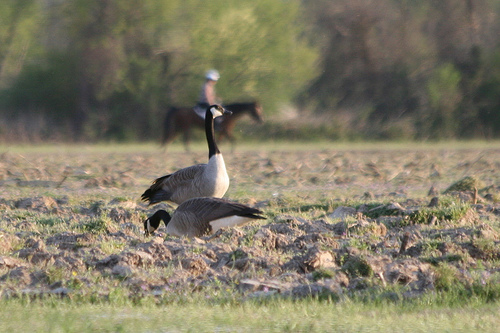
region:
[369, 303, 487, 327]
this is the grass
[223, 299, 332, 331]
the grass is green in color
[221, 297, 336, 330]
the grass is short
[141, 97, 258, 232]
these are birds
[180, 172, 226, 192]
the feathers are white in color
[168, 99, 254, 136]
this is a horse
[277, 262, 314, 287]
these are rocks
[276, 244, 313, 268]
the rocks are grey in color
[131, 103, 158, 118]
these are trees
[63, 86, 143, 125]
the trees are green in color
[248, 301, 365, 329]
Green grass on the ground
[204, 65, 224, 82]
Person wearing a white helmet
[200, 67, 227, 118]
Person sitting on a horse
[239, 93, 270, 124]
Horse head looking right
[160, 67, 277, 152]
Horse with a rider walking right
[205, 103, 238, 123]
Canadian goose head looking right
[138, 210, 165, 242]
Canadian goose eating grass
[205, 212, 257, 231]
White underside of a goose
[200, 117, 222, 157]
Canadian goose's black neck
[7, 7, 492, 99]
Trees behind a field of grass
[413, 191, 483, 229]
part of a ground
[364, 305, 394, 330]
part of some grass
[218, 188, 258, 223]
part of a tail wing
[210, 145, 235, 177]
part of a neck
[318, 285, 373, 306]
edge of a grass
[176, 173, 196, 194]
part of a feather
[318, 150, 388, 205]
part of a ground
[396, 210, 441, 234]
part of a ground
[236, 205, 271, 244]
part of a tail wing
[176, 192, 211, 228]
part of a wing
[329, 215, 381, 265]
part of a ground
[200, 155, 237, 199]
chest of a bird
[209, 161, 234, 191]
chest of a bird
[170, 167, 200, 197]
part of a feather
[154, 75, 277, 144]
A man riding a horse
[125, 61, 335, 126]
A man riding a horse